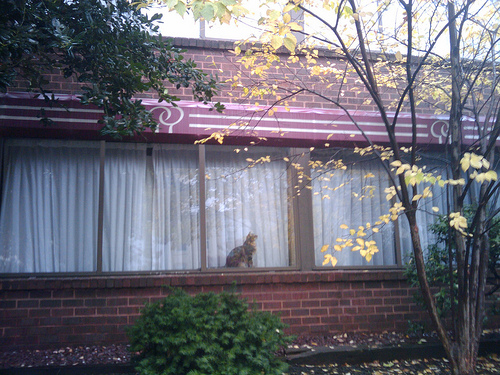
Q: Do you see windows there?
A: Yes, there is a window.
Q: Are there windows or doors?
A: Yes, there is a window.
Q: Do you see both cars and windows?
A: No, there is a window but no cars.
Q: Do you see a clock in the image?
A: No, there are no clocks.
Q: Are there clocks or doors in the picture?
A: No, there are no clocks or doors.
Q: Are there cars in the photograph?
A: No, there are no cars.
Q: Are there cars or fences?
A: No, there are no cars or fences.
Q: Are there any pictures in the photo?
A: No, there are no pictures.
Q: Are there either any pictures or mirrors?
A: No, there are no pictures or mirrors.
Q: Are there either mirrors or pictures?
A: No, there are no pictures or mirrors.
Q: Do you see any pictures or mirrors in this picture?
A: No, there are no pictures or mirrors.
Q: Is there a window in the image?
A: Yes, there is a window.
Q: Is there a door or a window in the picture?
A: Yes, there is a window.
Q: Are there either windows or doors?
A: Yes, there is a window.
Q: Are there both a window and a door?
A: No, there is a window but no doors.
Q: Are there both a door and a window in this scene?
A: No, there is a window but no doors.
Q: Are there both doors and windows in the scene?
A: No, there is a window but no doors.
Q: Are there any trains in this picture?
A: No, there are no trains.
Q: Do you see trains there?
A: No, there are no trains.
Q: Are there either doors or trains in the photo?
A: No, there are no trains or doors.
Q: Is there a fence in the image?
A: No, there are no fences.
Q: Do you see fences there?
A: No, there are no fences.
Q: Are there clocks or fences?
A: No, there are no fences or clocks.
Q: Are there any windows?
A: Yes, there are windows.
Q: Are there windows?
A: Yes, there are windows.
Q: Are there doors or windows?
A: Yes, there are windows.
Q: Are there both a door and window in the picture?
A: No, there are windows but no doors.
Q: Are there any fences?
A: No, there are no fences.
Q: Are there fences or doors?
A: No, there are no fences or doors.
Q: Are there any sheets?
A: No, there are no sheets.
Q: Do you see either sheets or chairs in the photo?
A: No, there are no sheets or chairs.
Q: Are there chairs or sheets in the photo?
A: No, there are no sheets or chairs.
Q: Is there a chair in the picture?
A: No, there are no chairs.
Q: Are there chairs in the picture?
A: No, there are no chairs.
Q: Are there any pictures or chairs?
A: No, there are no chairs or pictures.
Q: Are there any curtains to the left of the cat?
A: Yes, there is a curtain to the left of the cat.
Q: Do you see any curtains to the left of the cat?
A: Yes, there is a curtain to the left of the cat.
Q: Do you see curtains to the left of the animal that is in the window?
A: Yes, there is a curtain to the left of the cat.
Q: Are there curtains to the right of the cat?
A: No, the curtain is to the left of the cat.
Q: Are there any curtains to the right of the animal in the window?
A: No, the curtain is to the left of the cat.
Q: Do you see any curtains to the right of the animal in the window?
A: No, the curtain is to the left of the cat.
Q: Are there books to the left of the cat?
A: No, there is a curtain to the left of the cat.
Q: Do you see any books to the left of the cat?
A: No, there is a curtain to the left of the cat.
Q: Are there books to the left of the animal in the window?
A: No, there is a curtain to the left of the cat.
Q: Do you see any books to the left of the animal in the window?
A: No, there is a curtain to the left of the cat.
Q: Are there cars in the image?
A: No, there are no cars.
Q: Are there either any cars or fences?
A: No, there are no cars or fences.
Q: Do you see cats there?
A: Yes, there is a cat.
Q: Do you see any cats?
A: Yes, there is a cat.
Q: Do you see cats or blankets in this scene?
A: Yes, there is a cat.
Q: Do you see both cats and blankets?
A: No, there is a cat but no blankets.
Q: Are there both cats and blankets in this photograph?
A: No, there is a cat but no blankets.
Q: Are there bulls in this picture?
A: No, there are no bulls.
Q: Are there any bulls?
A: No, there are no bulls.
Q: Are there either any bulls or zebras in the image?
A: No, there are no bulls or zebras.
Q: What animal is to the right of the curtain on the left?
A: The animal is a cat.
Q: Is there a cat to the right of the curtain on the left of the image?
A: Yes, there is a cat to the right of the curtain.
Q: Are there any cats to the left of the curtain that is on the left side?
A: No, the cat is to the right of the curtain.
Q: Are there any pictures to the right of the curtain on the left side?
A: No, there is a cat to the right of the curtain.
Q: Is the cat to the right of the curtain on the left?
A: Yes, the cat is to the right of the curtain.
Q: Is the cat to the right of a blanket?
A: No, the cat is to the right of the curtain.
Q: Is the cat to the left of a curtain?
A: No, the cat is to the right of a curtain.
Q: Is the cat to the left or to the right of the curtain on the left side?
A: The cat is to the right of the curtain.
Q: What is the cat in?
A: The cat is in the window.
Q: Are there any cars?
A: No, there are no cars.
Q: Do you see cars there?
A: No, there are no cars.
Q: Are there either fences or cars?
A: No, there are no cars or fences.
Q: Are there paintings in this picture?
A: No, there are no paintings.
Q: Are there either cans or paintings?
A: No, there are no paintings or cans.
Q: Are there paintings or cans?
A: No, there are no paintings or cans.